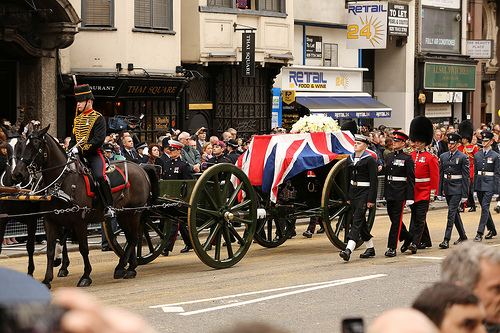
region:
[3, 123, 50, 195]
2 horses heads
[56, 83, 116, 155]
a guy in yellow and black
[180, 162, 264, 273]
a wagon wheel.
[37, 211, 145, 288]
horses legs.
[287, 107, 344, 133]
flowers.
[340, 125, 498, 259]
five men walking.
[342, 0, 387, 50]
retail 24 sign.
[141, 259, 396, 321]
white lines on road.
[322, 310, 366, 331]
top of a cell phone.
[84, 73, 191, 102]
Thai Square sign.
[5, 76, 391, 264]
horse drawn carriage funeral procession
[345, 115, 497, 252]
Five men walking beside casket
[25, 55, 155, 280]
man on brown horse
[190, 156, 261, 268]
wheel on carriage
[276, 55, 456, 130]
Retail 24 Food and Wine Store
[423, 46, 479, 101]
sign in background of funeral procession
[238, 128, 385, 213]
casket on carriage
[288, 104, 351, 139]
white flowers on flag of casket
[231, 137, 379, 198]
British flag covering casket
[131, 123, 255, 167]
people watching the funeral procession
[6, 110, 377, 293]
two horses pulling a wagon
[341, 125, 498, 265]
a line of uniformed men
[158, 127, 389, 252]
a coffin on the wagon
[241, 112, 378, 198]
white flowers on a coffin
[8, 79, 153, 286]
a man in uniform riding a horse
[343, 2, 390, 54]
a sign with the number 24 on it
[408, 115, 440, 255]
man wearing a black fuzzy hat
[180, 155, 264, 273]
a big wagon wheel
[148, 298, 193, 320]
a white diamond shape on the road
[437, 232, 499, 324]
a man with grey hair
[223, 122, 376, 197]
British flag on coffin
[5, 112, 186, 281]
Two horses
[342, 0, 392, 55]
Retail 24 signage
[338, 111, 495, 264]
British soldier in formal dress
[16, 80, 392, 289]
Horse and carriage funeral procession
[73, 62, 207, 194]
That Square restaurant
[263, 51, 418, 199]
Retail food & wine store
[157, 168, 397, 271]
Green carriage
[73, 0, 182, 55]
Black window shutters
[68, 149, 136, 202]
Black and red horse blanket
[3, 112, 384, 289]
horses pulling a wagon with a coffin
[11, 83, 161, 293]
a man riding a horse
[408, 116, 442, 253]
a man wearing a tall black hat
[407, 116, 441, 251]
a man wearing a red jacket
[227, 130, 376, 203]
a coffin covered with a flag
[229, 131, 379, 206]
a red, white and blue flag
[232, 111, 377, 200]
white flowers on top of a coffin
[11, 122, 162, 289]
a horse with a black and red saddle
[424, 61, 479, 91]
a green and yellow sign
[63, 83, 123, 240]
a man wearing a black and yellow jacket